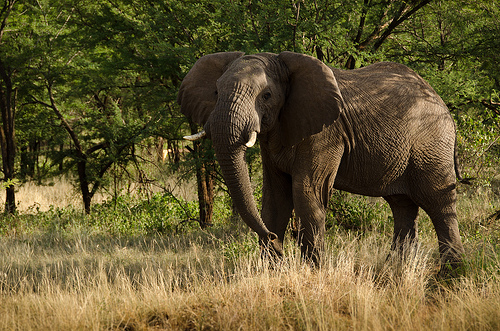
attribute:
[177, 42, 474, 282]
elephant — brownish gray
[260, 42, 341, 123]
ears —  large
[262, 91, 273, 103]
black eye —    black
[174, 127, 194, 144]
tusk — ivory, pointed